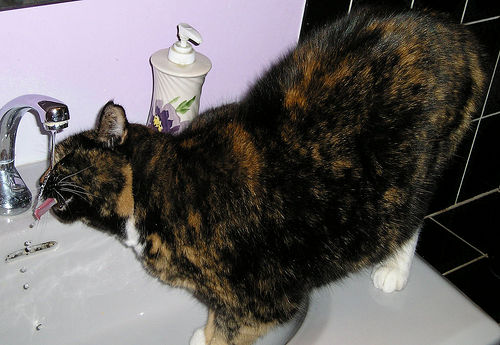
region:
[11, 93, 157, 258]
a cat drinking water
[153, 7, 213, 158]
liquid in the white color bottle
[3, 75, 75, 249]
steel tap fixed in the wall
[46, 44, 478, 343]
a cat standing on the washbasin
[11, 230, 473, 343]
white color washbasin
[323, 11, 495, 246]
black color wall tiles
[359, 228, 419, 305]
leg of the cat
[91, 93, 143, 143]
ear of the cat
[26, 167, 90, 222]
nose and mouth of the cat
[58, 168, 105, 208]
mustache of the cat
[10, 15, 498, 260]
this photo of the cat might be altered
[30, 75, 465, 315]
the cat is brown and black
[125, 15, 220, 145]
the soap bottle is white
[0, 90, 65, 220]
the facuet is on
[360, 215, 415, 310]
the cat has white feet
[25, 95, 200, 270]
the cat is drinking from a faucet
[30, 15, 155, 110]
this is a white wall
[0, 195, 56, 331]
water dripping form the cat's tounge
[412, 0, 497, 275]
the tile behind the cat is black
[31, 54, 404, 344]
the cat is standing on the sink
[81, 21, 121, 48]
this is the sink wall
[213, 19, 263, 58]
the wall is white in color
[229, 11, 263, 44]
the wall is clean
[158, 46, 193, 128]
this is a soap container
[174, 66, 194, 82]
the container is made of plastic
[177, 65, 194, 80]
the container is white in color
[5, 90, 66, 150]
this is a tap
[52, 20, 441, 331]
this is a cat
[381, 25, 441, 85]
the fur is black and brown in color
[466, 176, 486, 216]
the wall is made of tiles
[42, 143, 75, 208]
This cat is drinking the water here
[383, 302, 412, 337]
There is a white sink that is visible here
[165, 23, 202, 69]
There is a container of soap here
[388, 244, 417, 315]
The cat has white feet that are visible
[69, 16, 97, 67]
This wall is most definitely purple here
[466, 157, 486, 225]
There is black tile that is visible here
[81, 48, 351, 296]
Jackson Mingus took this photo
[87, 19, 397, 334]
This photo was taken in the state of Ohio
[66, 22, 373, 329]
This photo was taken in the city of Dayton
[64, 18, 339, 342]
This photo will soon win an award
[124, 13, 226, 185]
A white soap dispenser with flowered design.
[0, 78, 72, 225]
A faucet is running water.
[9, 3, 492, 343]
A calico cat is drinking water.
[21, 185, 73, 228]
The tongue of a calico cat.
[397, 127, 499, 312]
Black tile is on the walls.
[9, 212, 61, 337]
Drops of water are falling.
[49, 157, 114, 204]
Long white whiskers on a calico cat.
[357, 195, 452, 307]
Solid white paw on a calico cat.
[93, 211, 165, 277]
White patch of fur on a calico cat.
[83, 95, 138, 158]
The left ear of a calico cat.